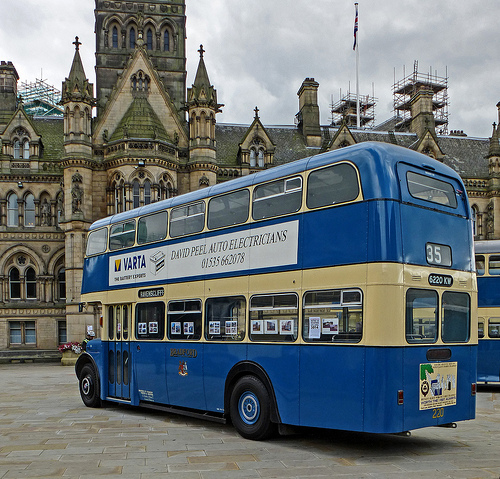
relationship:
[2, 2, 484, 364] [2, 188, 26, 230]
building has window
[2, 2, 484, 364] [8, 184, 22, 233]
building has window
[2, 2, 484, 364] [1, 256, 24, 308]
building has window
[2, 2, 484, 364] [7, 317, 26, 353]
building has window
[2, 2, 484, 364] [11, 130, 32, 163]
building has window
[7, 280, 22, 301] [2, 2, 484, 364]
window on building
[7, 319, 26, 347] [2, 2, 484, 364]
window on building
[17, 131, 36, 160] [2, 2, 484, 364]
window on building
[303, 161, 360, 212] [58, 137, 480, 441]
window on bus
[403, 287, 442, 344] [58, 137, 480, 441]
window on bus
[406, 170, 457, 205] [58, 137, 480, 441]
window on bus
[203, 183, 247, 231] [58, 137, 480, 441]
window on bus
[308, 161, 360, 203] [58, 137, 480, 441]
window on bus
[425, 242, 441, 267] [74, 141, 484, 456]
number 35 on bus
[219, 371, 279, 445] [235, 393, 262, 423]
tire has rim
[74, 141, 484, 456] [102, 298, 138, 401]
bus has door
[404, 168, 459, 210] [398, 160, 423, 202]
window has curve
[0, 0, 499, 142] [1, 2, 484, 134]
cloud hanging in sky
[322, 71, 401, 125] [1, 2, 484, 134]
cloud hanging in sky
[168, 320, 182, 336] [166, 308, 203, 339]
sticker stuck on window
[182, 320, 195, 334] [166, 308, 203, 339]
sticker stuck on window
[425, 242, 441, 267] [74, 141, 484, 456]
number 35 lit up on back of bus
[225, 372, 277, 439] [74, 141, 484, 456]
wheel mounted on bus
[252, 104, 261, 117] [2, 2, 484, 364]
cross standing on top of building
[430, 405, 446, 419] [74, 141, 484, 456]
number 220 painted on back of bus